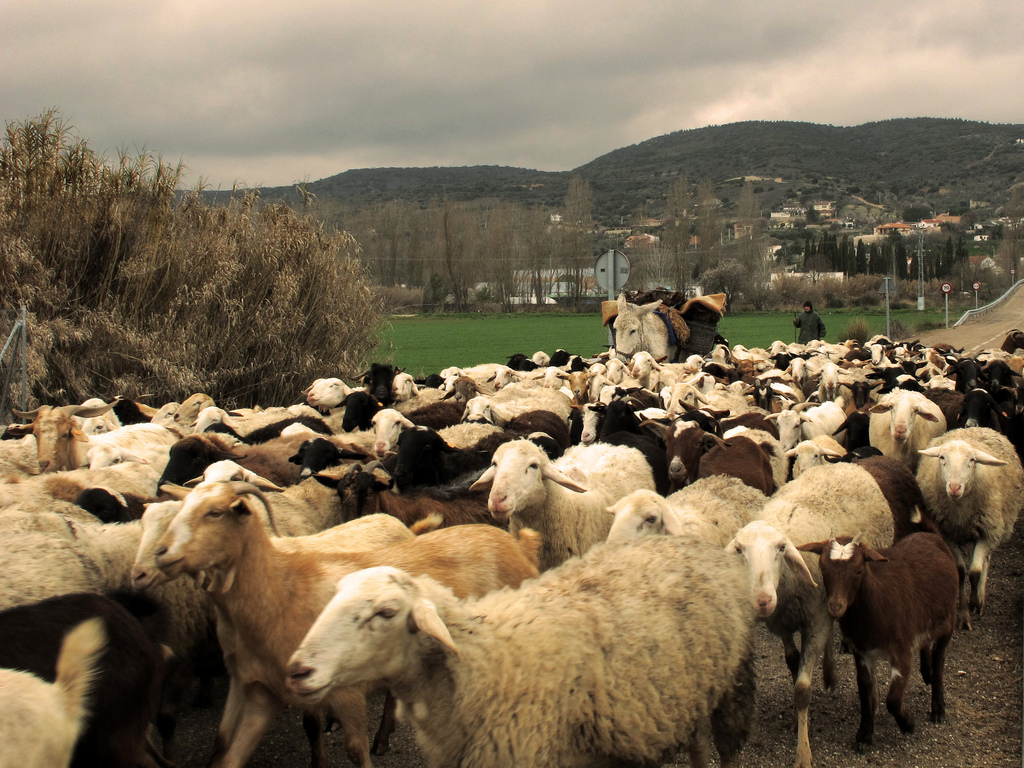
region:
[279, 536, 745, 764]
A white sheep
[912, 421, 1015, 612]
A white sheep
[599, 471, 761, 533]
A white sheep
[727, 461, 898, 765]
A white sheep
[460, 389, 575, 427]
A white sheep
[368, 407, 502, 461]
A white sheep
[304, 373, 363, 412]
A white sheep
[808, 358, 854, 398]
A white sheep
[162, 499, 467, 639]
sheep in the field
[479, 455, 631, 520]
sheep in the field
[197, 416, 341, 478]
sheep in the field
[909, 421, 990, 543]
sheep in the field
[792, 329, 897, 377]
sheep in the field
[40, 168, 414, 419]
the trees are dying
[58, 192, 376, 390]
the trees are dry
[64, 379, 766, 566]
this is a herd of sheep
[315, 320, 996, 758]
the sheep are varied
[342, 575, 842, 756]
the sheep is shaggy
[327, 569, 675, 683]
the sheep is white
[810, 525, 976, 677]
the small sheep is brown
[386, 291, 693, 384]
the field is grassy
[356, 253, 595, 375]
the field is green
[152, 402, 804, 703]
these are livestock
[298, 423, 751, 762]
these are a herd of sheep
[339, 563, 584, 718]
the sheep is white and gray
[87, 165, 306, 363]
these trees are tall and gray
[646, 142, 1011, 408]
the background is a town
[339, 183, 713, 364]
these trees are lined up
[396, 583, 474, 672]
White ear of a sheep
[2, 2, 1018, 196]
The sky is very cloudy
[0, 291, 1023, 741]
a heard of sheep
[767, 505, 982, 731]
a small brown sheep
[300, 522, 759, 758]
a tan furry sheep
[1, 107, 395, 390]
bush on the side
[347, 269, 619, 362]
field in the background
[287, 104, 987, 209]
mountains in the background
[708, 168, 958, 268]
buildings in the distance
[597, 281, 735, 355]
horse behind the sheep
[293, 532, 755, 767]
sheep walks on road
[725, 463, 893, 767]
sheep walks on road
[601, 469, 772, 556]
sheep walks on road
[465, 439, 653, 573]
sheep walks on road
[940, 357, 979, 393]
sheep walks on road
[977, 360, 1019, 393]
sheep walks on road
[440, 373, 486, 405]
sheep walks on road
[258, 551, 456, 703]
sheep head in the crowd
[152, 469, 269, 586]
sheep head in the crowd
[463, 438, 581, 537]
sheep head in the crowd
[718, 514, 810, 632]
sheep head in the crowd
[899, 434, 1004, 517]
sheep head in the crowd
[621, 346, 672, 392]
sheep head in the crowd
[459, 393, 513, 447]
sheep head in the crowd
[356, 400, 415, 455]
sheep head in the crowd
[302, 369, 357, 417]
sheep head in the crowd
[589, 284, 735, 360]
donkey with brown packs on its back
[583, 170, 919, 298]
distant houses on a hill side